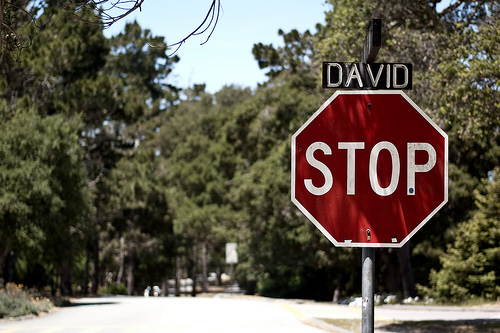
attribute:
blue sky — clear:
[25, 0, 498, 181]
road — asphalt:
[0, 287, 497, 331]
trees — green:
[2, 4, 498, 304]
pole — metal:
[353, 244, 405, 329]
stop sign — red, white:
[268, 80, 457, 267]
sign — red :
[307, 83, 430, 248]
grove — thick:
[5, 4, 498, 308]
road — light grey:
[97, 300, 259, 329]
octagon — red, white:
[282, 81, 458, 256]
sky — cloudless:
[228, 0, 291, 62]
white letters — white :
[303, 134, 437, 197]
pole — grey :
[359, 248, 376, 331]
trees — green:
[166, 106, 207, 137]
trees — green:
[265, 153, 288, 190]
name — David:
[317, 60, 418, 94]